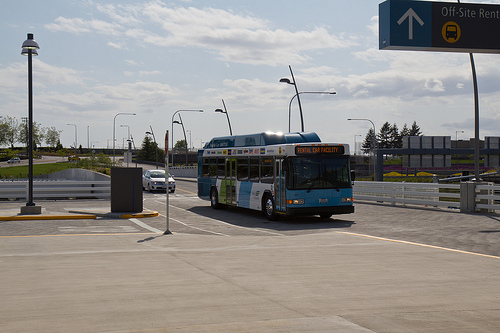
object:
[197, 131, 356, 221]
bus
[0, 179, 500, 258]
roadway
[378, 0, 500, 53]
sign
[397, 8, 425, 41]
arrow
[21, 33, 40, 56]
street light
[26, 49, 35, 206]
pole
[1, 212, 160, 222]
curb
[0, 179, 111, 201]
fence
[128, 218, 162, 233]
lines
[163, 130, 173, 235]
sign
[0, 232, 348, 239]
curb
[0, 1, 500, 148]
clouds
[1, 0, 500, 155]
sky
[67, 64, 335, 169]
lights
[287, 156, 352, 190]
window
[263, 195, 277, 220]
wheel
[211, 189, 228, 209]
tire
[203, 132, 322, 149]
top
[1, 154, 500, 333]
land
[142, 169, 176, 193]
car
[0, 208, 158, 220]
median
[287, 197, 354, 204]
headlights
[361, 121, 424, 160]
trees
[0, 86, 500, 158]
distance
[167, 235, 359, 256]
corner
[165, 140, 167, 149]
word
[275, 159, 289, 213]
doors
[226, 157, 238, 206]
doors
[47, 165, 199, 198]
bridge